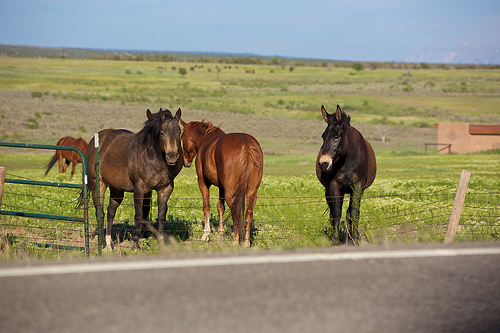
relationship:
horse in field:
[315, 102, 378, 245] [0, 57, 497, 257]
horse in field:
[73, 102, 183, 257] [0, 57, 497, 257]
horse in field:
[176, 117, 264, 247] [0, 57, 497, 257]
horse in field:
[46, 130, 88, 177] [0, 57, 497, 257]